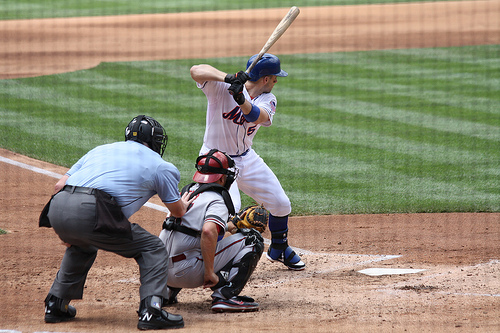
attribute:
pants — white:
[196, 148, 293, 217]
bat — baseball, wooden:
[232, 0, 303, 95]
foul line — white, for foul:
[1, 152, 323, 259]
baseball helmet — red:
[187, 141, 240, 186]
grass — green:
[317, 60, 499, 194]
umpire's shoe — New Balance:
[140, 309, 185, 331]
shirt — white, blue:
[192, 67, 277, 159]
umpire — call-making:
[31, 115, 176, 332]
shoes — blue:
[266, 242, 307, 272]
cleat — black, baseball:
[210, 294, 256, 313]